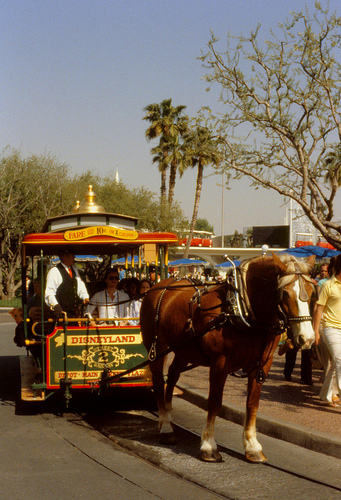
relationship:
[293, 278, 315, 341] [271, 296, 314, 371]
stripe on nose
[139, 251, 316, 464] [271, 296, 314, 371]
horse has nose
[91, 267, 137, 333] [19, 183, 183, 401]
man in front seat of carriage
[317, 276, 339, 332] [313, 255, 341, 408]
shirt on people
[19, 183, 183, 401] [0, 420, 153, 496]
carriage on road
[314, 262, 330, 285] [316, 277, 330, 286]
man wearing shirt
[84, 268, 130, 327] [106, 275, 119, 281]
man in glasses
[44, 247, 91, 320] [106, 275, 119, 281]
man in glasses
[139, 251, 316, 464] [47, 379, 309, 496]
horse on road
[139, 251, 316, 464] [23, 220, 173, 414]
horse pulling carriage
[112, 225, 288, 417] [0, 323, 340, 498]
horse on street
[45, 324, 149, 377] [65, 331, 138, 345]
sign says disneyland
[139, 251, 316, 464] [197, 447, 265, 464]
horse says hooves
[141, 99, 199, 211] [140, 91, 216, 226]
palm tree in group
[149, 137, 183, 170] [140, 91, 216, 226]
palm tree in group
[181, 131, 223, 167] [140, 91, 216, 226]
palm tree in group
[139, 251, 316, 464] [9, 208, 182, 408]
horse pulls carriage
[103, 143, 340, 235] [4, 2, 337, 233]
clouds in sky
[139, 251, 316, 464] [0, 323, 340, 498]
horse on street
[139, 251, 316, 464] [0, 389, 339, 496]
horse on street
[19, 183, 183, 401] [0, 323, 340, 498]
carriage on street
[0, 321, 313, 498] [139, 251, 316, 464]
road with horse